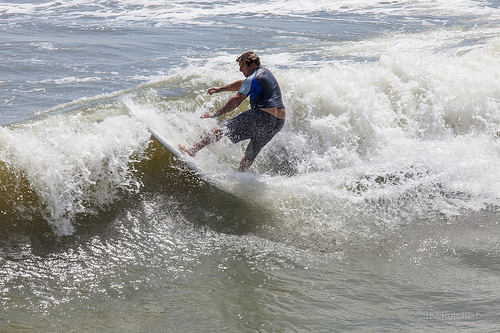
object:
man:
[178, 51, 287, 174]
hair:
[237, 52, 262, 64]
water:
[0, 2, 498, 331]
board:
[114, 99, 284, 208]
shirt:
[235, 69, 282, 110]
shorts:
[216, 105, 286, 161]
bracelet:
[211, 111, 221, 117]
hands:
[200, 111, 217, 121]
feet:
[177, 142, 202, 157]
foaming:
[309, 77, 432, 169]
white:
[146, 124, 179, 153]